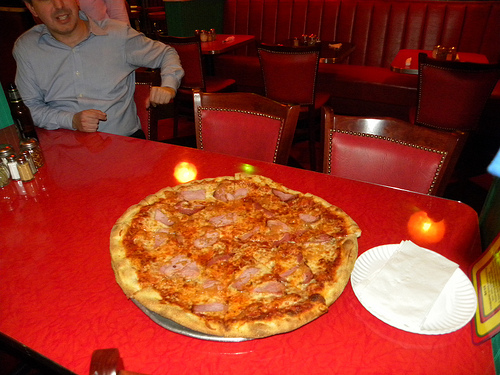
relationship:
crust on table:
[105, 171, 357, 337] [0, 130, 493, 367]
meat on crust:
[251, 275, 283, 292] [105, 171, 357, 337]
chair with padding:
[326, 74, 467, 215] [324, 128, 444, 189]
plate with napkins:
[349, 242, 478, 352] [379, 235, 462, 318]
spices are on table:
[1, 131, 43, 192] [0, 130, 493, 367]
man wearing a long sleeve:
[13, 2, 185, 140] [14, 25, 185, 135]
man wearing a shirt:
[13, 2, 185, 140] [12, 21, 183, 133]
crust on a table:
[105, 171, 357, 337] [0, 130, 493, 367]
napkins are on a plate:
[369, 239, 459, 319] [350, 243, 480, 336]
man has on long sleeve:
[13, 2, 185, 140] [14, 10, 185, 132]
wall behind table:
[221, 4, 496, 72] [324, 336, 416, 369]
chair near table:
[196, 97, 287, 162] [41, 142, 101, 344]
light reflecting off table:
[174, 154, 197, 184] [46, 127, 498, 368]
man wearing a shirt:
[13, 0, 186, 139] [27, 27, 132, 126]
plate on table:
[348, 227, 493, 361] [0, 130, 493, 367]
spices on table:
[0, 131, 43, 188] [0, 130, 493, 367]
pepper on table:
[17, 137, 44, 167] [0, 130, 493, 367]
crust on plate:
[105, 171, 357, 337] [150, 312, 171, 326]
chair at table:
[192, 88, 301, 166] [363, 189, 447, 222]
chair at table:
[192, 88, 301, 166] [0, 130, 493, 367]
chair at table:
[192, 88, 301, 166] [5, 82, 497, 372]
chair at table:
[256, 39, 323, 109] [5, 104, 479, 371]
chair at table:
[157, 34, 237, 89] [5, 104, 479, 371]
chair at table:
[413, 49, 494, 138] [5, 104, 479, 371]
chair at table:
[321, 107, 466, 198] [5, 104, 479, 371]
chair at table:
[192, 88, 301, 166] [5, 104, 479, 371]